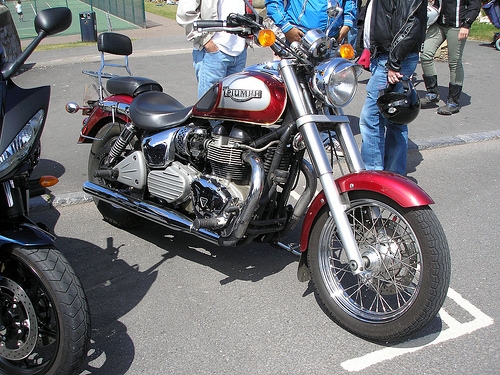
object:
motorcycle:
[64, 0, 449, 346]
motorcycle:
[0, 7, 92, 375]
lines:
[339, 317, 494, 372]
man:
[355, 0, 425, 176]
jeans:
[359, 52, 412, 177]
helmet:
[376, 74, 420, 127]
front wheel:
[306, 188, 451, 341]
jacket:
[265, 0, 358, 34]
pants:
[420, 23, 467, 86]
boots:
[434, 79, 464, 115]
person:
[420, 0, 483, 114]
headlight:
[328, 60, 358, 108]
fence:
[1, 0, 148, 40]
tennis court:
[3, 1, 144, 45]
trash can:
[79, 12, 100, 43]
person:
[14, 0, 24, 22]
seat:
[130, 90, 195, 129]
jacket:
[356, 0, 429, 71]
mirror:
[34, 7, 72, 36]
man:
[175, 0, 252, 102]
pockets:
[203, 47, 228, 63]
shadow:
[99, 206, 296, 286]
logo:
[222, 85, 262, 103]